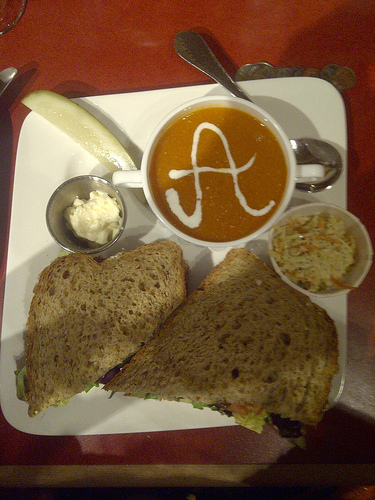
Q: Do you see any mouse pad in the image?
A: No, there are no mouse pads.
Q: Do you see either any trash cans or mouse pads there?
A: No, there are no mouse pads or trash cans.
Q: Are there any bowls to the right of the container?
A: Yes, there is a bowl to the right of the container.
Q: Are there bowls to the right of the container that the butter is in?
A: Yes, there is a bowl to the right of the container.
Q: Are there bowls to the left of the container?
A: No, the bowl is to the right of the container.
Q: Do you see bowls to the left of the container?
A: No, the bowl is to the right of the container.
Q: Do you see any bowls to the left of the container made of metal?
A: No, the bowl is to the right of the container.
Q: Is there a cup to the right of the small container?
A: No, there is a bowl to the right of the container.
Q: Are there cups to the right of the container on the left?
A: No, there is a bowl to the right of the container.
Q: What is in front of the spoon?
A: The bowl is in front of the spoon.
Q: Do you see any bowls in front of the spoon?
A: Yes, there is a bowl in front of the spoon.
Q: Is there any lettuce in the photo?
A: Yes, there is lettuce.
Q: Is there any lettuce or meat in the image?
A: Yes, there is lettuce.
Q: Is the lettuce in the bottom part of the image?
A: Yes, the lettuce is in the bottom of the image.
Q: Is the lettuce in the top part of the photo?
A: No, the lettuce is in the bottom of the image.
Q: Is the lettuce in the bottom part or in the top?
A: The lettuce is in the bottom of the image.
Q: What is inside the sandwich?
A: The lettuce is inside the sandwich.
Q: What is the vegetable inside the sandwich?
A: The vegetable is lettuce.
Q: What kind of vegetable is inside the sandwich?
A: The vegetable is lettuce.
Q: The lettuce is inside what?
A: The lettuce is inside the sandwich.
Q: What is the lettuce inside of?
A: The lettuce is inside the sandwich.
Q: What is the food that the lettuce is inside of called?
A: The food is a sandwich.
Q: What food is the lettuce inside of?
A: The lettuce is inside the sandwich.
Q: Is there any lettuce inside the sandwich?
A: Yes, there is lettuce inside the sandwich.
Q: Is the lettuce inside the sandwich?
A: Yes, the lettuce is inside the sandwich.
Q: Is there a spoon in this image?
A: Yes, there is a spoon.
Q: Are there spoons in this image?
A: Yes, there is a spoon.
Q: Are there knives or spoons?
A: Yes, there is a spoon.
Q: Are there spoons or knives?
A: Yes, there is a spoon.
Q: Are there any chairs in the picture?
A: No, there are no chairs.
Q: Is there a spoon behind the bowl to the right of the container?
A: Yes, there is a spoon behind the bowl.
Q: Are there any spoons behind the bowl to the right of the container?
A: Yes, there is a spoon behind the bowl.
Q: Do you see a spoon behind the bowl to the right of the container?
A: Yes, there is a spoon behind the bowl.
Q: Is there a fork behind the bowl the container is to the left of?
A: No, there is a spoon behind the bowl.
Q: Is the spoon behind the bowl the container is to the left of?
A: Yes, the spoon is behind the bowl.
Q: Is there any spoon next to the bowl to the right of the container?
A: Yes, there is a spoon next to the bowl.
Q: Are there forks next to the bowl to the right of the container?
A: No, there is a spoon next to the bowl.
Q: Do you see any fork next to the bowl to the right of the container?
A: No, there is a spoon next to the bowl.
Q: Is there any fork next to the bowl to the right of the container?
A: No, there is a spoon next to the bowl.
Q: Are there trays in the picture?
A: No, there are no trays.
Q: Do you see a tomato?
A: Yes, there are tomatoes.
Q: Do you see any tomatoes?
A: Yes, there are tomatoes.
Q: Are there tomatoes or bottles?
A: Yes, there are tomatoes.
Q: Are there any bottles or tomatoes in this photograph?
A: Yes, there are tomatoes.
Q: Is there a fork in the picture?
A: No, there are no forks.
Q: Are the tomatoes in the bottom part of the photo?
A: Yes, the tomatoes are in the bottom of the image.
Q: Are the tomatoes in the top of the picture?
A: No, the tomatoes are in the bottom of the image.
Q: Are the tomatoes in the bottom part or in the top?
A: The tomatoes are in the bottom of the image.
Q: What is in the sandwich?
A: The tomatoes are in the sandwich.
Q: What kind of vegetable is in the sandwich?
A: The vegetables are tomatoes.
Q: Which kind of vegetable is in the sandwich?
A: The vegetables are tomatoes.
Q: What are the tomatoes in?
A: The tomatoes are in the sandwich.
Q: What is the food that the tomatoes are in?
A: The food is a sandwich.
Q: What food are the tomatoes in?
A: The tomatoes are in the sandwich.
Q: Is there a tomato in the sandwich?
A: Yes, there are tomatoes in the sandwich.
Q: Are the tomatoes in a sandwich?
A: Yes, the tomatoes are in a sandwich.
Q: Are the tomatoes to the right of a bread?
A: Yes, the tomatoes are to the right of a bread.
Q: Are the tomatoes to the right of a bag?
A: No, the tomatoes are to the right of a bread.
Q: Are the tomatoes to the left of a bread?
A: No, the tomatoes are to the right of a bread.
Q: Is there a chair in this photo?
A: No, there are no chairs.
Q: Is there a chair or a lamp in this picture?
A: No, there are no chairs or lamps.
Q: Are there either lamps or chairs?
A: No, there are no chairs or lamps.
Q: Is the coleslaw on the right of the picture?
A: Yes, the coleslaw is on the right of the image.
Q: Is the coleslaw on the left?
A: No, the coleslaw is on the right of the image.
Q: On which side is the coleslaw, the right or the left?
A: The coleslaw is on the right of the image.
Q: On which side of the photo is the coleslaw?
A: The coleslaw is on the right of the image.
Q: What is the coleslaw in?
A: The coleslaw is in the bowl.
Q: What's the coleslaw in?
A: The coleslaw is in the bowl.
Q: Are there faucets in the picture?
A: No, there are no faucets.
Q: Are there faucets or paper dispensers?
A: No, there are no faucets or paper dispensers.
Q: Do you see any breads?
A: Yes, there is a bread.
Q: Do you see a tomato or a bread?
A: Yes, there is a bread.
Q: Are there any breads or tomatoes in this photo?
A: Yes, there is a bread.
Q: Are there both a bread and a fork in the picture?
A: No, there is a bread but no forks.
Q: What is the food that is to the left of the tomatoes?
A: The food is a bread.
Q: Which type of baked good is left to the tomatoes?
A: The food is a bread.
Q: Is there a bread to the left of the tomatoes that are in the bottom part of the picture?
A: Yes, there is a bread to the left of the tomatoes.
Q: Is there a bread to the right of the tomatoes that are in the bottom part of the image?
A: No, the bread is to the left of the tomatoes.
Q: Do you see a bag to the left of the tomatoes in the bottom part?
A: No, there is a bread to the left of the tomatoes.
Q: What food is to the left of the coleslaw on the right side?
A: The food is a bread.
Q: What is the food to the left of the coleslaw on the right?
A: The food is a bread.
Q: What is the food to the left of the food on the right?
A: The food is a bread.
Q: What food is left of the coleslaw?
A: The food is a bread.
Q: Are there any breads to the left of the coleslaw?
A: Yes, there is a bread to the left of the coleslaw.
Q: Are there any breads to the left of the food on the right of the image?
A: Yes, there is a bread to the left of the coleslaw.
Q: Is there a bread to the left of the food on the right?
A: Yes, there is a bread to the left of the coleslaw.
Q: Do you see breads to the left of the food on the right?
A: Yes, there is a bread to the left of the coleslaw.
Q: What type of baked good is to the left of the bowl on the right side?
A: The food is a bread.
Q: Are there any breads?
A: Yes, there is a bread.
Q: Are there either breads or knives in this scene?
A: Yes, there is a bread.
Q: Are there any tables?
A: Yes, there is a table.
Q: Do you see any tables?
A: Yes, there is a table.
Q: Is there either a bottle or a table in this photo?
A: Yes, there is a table.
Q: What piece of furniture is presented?
A: The piece of furniture is a table.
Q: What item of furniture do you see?
A: The piece of furniture is a table.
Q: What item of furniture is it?
A: The piece of furniture is a table.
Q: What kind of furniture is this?
A: This is a table.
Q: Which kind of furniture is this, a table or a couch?
A: This is a table.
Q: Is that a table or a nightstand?
A: That is a table.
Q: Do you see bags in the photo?
A: No, there are no bags.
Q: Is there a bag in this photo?
A: No, there are no bags.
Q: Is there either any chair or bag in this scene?
A: No, there are no bags or chairs.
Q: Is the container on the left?
A: Yes, the container is on the left of the image.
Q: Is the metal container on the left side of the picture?
A: Yes, the container is on the left of the image.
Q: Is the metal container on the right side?
A: No, the container is on the left of the image.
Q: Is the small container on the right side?
A: No, the container is on the left of the image.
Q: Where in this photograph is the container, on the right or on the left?
A: The container is on the left of the image.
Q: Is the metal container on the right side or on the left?
A: The container is on the left of the image.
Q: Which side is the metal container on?
A: The container is on the left of the image.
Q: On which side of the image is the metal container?
A: The container is on the left of the image.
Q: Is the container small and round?
A: Yes, the container is small and round.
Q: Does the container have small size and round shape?
A: Yes, the container is small and round.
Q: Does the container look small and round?
A: Yes, the container is small and round.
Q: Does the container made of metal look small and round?
A: Yes, the container is small and round.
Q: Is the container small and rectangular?
A: No, the container is small but round.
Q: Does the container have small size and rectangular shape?
A: No, the container is small but round.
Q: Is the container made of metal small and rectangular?
A: No, the container is small but round.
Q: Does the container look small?
A: Yes, the container is small.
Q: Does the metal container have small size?
A: Yes, the container is small.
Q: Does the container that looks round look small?
A: Yes, the container is small.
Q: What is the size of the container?
A: The container is small.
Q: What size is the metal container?
A: The container is small.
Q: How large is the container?
A: The container is small.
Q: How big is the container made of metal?
A: The container is small.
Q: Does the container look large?
A: No, the container is small.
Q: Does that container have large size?
A: No, the container is small.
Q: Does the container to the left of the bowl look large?
A: No, the container is small.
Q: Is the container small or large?
A: The container is small.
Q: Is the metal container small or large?
A: The container is small.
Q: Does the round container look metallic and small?
A: Yes, the container is metallic and small.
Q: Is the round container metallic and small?
A: Yes, the container is metallic and small.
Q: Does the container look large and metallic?
A: No, the container is metallic but small.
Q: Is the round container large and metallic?
A: No, the container is metallic but small.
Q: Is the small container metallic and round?
A: Yes, the container is metallic and round.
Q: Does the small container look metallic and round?
A: Yes, the container is metallic and round.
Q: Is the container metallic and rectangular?
A: No, the container is metallic but round.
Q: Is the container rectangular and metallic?
A: No, the container is metallic but round.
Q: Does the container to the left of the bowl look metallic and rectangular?
A: No, the container is metallic but round.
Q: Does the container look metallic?
A: Yes, the container is metallic.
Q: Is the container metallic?
A: Yes, the container is metallic.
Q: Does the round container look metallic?
A: Yes, the container is metallic.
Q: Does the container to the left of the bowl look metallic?
A: Yes, the container is metallic.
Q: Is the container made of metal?
A: Yes, the container is made of metal.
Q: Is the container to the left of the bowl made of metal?
A: Yes, the container is made of metal.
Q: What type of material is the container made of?
A: The container is made of metal.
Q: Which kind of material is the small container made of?
A: The container is made of metal.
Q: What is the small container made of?
A: The container is made of metal.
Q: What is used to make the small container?
A: The container is made of metal.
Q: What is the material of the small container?
A: The container is made of metal.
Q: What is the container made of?
A: The container is made of metal.